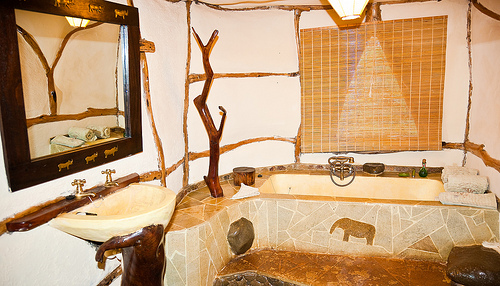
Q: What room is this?
A: Bathroom.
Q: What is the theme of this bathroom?
A: Native American.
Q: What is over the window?
A: Shade.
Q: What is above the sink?
A: Mirror.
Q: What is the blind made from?
A: Bamboo.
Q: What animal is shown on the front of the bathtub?
A: Elephant.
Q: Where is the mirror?
A: Over the sink.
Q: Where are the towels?
A: Edge of the bathtub.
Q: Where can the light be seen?
A: Through the mirror.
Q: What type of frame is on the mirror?
A: Wooden.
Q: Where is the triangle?
A: Behind the bathtub on the wall.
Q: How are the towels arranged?
A: Rolled and stacked.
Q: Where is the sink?
A: On the left wall.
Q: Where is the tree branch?
A: Against the wall and in the mirror.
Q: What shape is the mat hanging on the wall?
A: Square.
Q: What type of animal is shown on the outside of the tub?
A: Elephant.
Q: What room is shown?
A: Bathroom.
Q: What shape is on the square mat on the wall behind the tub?
A: Triangle.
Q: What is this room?
A: Bathroom.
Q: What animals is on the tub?
A: Elephant.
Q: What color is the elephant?
A: Brown.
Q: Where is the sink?
A: The left.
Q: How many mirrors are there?
A: One.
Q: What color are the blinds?
A: Brown.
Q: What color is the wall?
A: White.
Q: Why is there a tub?
A: For bathing.